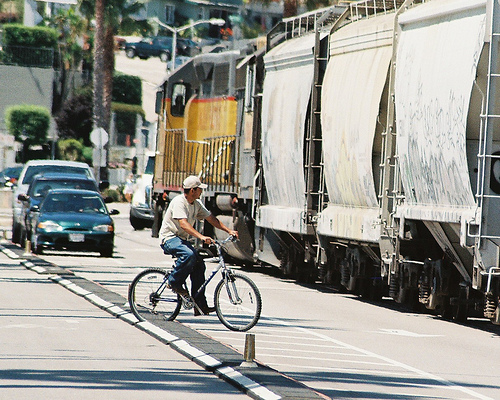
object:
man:
[158, 170, 241, 315]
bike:
[127, 233, 262, 330]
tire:
[212, 273, 263, 331]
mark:
[352, 336, 387, 363]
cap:
[179, 173, 211, 191]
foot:
[167, 273, 190, 296]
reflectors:
[246, 287, 254, 301]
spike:
[234, 306, 247, 316]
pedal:
[171, 291, 198, 308]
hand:
[197, 230, 214, 242]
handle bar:
[208, 232, 237, 249]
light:
[42, 220, 63, 232]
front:
[38, 215, 116, 248]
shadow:
[0, 365, 499, 398]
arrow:
[359, 326, 441, 338]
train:
[143, 25, 499, 328]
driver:
[172, 91, 188, 112]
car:
[31, 181, 115, 249]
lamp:
[173, 17, 226, 35]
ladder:
[473, 138, 497, 250]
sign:
[87, 127, 111, 147]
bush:
[2, 105, 52, 136]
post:
[91, 154, 113, 174]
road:
[293, 329, 499, 399]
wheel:
[98, 245, 113, 258]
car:
[13, 159, 91, 169]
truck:
[13, 158, 95, 242]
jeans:
[161, 237, 209, 311]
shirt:
[158, 193, 213, 239]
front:
[23, 163, 55, 172]